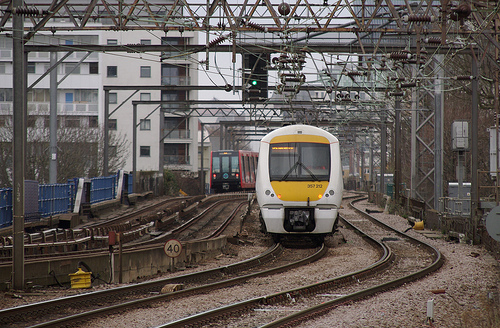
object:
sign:
[164, 239, 184, 259]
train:
[253, 122, 344, 250]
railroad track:
[1, 193, 443, 323]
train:
[210, 146, 259, 190]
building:
[1, 0, 205, 195]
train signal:
[248, 79, 266, 86]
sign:
[269, 144, 296, 154]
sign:
[218, 152, 233, 155]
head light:
[274, 192, 283, 201]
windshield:
[267, 140, 330, 181]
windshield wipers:
[280, 161, 317, 182]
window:
[106, 66, 119, 78]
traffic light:
[249, 78, 259, 87]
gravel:
[330, 307, 494, 328]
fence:
[1, 174, 136, 228]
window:
[268, 142, 298, 179]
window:
[137, 65, 155, 81]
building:
[362, 1, 499, 216]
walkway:
[230, 26, 421, 50]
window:
[136, 143, 152, 159]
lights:
[211, 171, 220, 180]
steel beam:
[430, 51, 449, 231]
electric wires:
[14, 37, 274, 83]